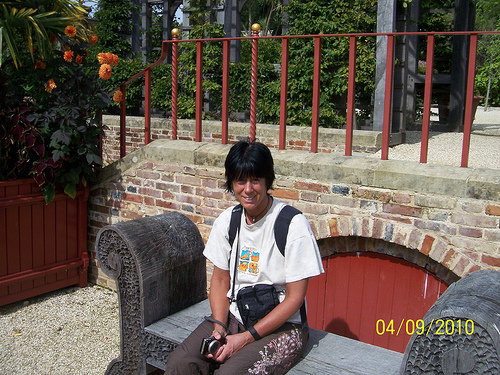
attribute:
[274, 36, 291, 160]
bar — metal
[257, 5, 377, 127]
tree — green, large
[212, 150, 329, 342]
woman — smiling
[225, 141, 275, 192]
hair — short, dark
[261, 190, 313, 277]
strap — black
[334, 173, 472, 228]
wall — brick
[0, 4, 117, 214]
flower — large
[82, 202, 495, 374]
bench — large, cement, gray 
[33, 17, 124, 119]
flowers — orange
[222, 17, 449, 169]
railings — metal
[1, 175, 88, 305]
planter — wooden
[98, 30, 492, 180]
fence — pink, metal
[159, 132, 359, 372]
woman — sitting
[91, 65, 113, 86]
flower — orange 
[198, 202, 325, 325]
t shirt — white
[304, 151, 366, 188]
brick — clay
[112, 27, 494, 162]
rail — long, red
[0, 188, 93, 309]
planter box — red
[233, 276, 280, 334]
fanny pack —  black fanny 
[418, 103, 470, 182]
walkway — paved